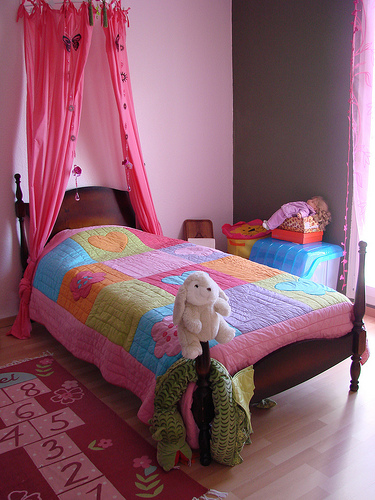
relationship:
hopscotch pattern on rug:
[8, 382, 128, 477] [6, 350, 205, 492]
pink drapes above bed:
[340, 8, 373, 106] [22, 178, 369, 423]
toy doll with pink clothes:
[260, 191, 333, 233] [265, 198, 316, 231]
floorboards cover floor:
[225, 408, 342, 498] [51, 377, 373, 495]